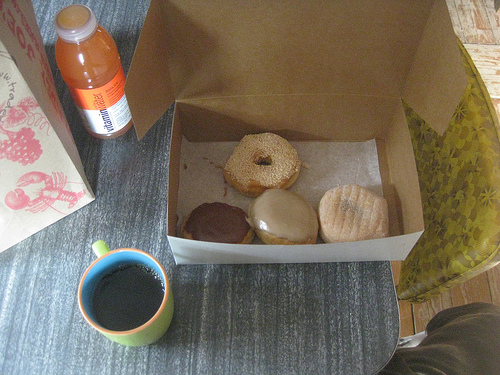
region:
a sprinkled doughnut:
[223, 133, 300, 196]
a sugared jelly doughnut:
[316, 183, 387, 245]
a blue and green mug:
[73, 241, 171, 347]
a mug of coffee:
[78, 238, 173, 347]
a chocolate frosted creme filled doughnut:
[183, 199, 250, 244]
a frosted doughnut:
[249, 184, 316, 244]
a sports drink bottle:
[50, 7, 130, 140]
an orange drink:
[50, 5, 132, 140]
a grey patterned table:
[1, 0, 398, 365]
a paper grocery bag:
[0, 0, 97, 261]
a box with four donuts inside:
[120, 0, 473, 277]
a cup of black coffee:
[73, 235, 175, 348]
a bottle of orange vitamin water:
[49, 3, 135, 143]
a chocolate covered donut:
[181, 199, 251, 249]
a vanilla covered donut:
[246, 187, 321, 245]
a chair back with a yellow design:
[386, 31, 498, 296]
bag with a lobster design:
[2, 165, 87, 217]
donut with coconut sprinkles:
[223, 132, 303, 188]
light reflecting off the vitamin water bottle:
[66, 24, 96, 92]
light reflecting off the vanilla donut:
[253, 216, 269, 231]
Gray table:
[3, 1, 400, 374]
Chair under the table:
[397, 36, 497, 303]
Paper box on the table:
[122, 1, 469, 264]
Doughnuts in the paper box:
[183, 131, 390, 246]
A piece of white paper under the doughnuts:
[177, 132, 389, 242]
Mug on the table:
[77, 240, 173, 347]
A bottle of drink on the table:
[55, 4, 132, 140]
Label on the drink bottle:
[76, 69, 129, 134]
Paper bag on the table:
[0, 1, 95, 256]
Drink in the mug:
[93, 265, 163, 332]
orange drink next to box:
[49, 0, 127, 151]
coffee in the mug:
[60, 243, 174, 325]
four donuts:
[197, 137, 363, 240]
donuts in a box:
[239, 113, 291, 148]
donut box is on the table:
[245, 256, 312, 281]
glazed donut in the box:
[261, 203, 299, 243]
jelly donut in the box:
[320, 180, 389, 239]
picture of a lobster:
[6, 162, 94, 235]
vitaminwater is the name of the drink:
[86, 81, 123, 137]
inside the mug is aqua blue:
[119, 252, 149, 270]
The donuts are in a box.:
[120, 0, 473, 269]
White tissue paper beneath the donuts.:
[171, 125, 390, 242]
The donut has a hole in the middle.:
[219, 126, 304, 198]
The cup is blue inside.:
[73, 235, 179, 349]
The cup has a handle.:
[71, 235, 177, 350]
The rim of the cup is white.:
[71, 237, 178, 351]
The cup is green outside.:
[73, 236, 178, 355]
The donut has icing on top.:
[181, 195, 253, 251]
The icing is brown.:
[181, 198, 250, 245]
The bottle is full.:
[50, 1, 137, 141]